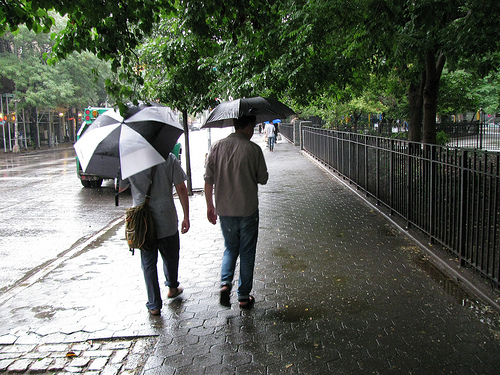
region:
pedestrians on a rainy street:
[13, 12, 489, 354]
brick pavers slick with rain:
[299, 211, 419, 304]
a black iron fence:
[325, 123, 459, 242]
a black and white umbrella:
[52, 92, 185, 172]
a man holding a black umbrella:
[197, 85, 300, 275]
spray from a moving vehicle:
[70, 171, 103, 202]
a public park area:
[342, 85, 486, 227]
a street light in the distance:
[2, 103, 40, 145]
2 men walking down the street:
[63, 70, 318, 328]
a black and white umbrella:
[67, 97, 185, 184]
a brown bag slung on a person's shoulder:
[125, 176, 165, 248]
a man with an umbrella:
[195, 93, 293, 307]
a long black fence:
[270, 115, 499, 303]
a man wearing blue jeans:
[213, 208, 261, 305]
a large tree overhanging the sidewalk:
[2, 14, 496, 147]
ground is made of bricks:
[5, 130, 492, 373]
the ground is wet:
[6, 127, 498, 372]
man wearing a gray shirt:
[203, 130, 270, 220]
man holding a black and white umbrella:
[193, 92, 291, 139]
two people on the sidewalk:
[40, 10, 364, 362]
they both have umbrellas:
[56, 64, 344, 335]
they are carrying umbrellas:
[47, 36, 351, 348]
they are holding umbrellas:
[65, 64, 303, 343]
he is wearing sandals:
[204, 278, 297, 326]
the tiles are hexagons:
[165, 330, 208, 353]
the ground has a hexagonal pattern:
[136, 240, 438, 336]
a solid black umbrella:
[177, 76, 302, 138]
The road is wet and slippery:
[11, 218, 114, 328]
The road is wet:
[17, 220, 113, 322]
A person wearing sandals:
[213, 279, 260, 314]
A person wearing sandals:
[132, 277, 197, 320]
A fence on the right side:
[304, 122, 498, 264]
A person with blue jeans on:
[213, 214, 265, 300]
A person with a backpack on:
[116, 200, 193, 287]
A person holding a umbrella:
[58, 96, 206, 315]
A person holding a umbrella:
[204, 102, 303, 313]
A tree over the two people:
[38, 5, 493, 215]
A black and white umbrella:
[73, 105, 172, 172]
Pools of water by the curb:
[65, 208, 130, 253]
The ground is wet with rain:
[0, 102, 480, 374]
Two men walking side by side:
[78, 95, 270, 305]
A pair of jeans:
[215, 212, 257, 294]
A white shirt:
[208, 132, 264, 220]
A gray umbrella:
[202, 96, 285, 127]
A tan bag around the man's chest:
[119, 155, 161, 252]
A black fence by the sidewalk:
[282, 116, 497, 298]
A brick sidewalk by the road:
[92, 146, 497, 371]